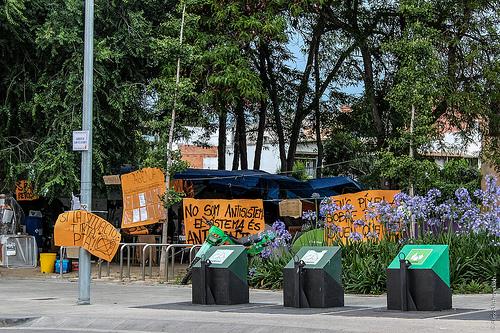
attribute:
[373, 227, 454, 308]
box — brown, green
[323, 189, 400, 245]
sign — orange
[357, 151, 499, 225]
flowers — purple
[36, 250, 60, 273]
bucket — orange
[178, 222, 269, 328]
bucket — yellow 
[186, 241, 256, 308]
box — black, green